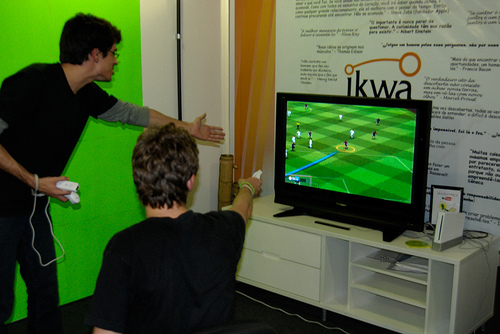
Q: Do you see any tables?
A: Yes, there is a table.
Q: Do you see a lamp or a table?
A: Yes, there is a table.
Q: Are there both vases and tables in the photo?
A: No, there is a table but no vases.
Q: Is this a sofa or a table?
A: This is a table.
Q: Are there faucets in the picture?
A: No, there are no faucets.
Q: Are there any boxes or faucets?
A: No, there are no faucets or boxes.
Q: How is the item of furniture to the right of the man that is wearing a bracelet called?
A: The piece of furniture is a drawer.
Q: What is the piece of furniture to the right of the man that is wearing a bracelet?
A: The piece of furniture is a drawer.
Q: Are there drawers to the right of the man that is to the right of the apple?
A: Yes, there is a drawer to the right of the man.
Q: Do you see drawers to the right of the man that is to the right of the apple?
A: Yes, there is a drawer to the right of the man.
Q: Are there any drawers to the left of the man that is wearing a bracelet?
A: No, the drawer is to the right of the man.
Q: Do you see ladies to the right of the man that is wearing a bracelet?
A: No, there is a drawer to the right of the man.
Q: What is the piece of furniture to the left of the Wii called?
A: The piece of furniture is a drawer.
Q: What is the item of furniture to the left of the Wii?
A: The piece of furniture is a drawer.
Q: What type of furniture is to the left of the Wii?
A: The piece of furniture is a drawer.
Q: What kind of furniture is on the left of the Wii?
A: The piece of furniture is a drawer.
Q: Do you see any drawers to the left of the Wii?
A: Yes, there is a drawer to the left of the Wii.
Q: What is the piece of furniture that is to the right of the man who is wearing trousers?
A: The piece of furniture is a drawer.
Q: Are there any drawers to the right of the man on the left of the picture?
A: Yes, there is a drawer to the right of the man.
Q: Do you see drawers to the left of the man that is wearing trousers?
A: No, the drawer is to the right of the man.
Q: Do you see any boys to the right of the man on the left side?
A: No, there is a drawer to the right of the man.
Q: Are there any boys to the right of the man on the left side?
A: No, there is a drawer to the right of the man.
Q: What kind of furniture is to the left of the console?
A: The piece of furniture is a drawer.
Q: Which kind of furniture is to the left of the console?
A: The piece of furniture is a drawer.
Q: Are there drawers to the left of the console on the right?
A: Yes, there is a drawer to the left of the console.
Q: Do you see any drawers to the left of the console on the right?
A: Yes, there is a drawer to the left of the console.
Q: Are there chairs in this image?
A: No, there are no chairs.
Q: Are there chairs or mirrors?
A: No, there are no chairs or mirrors.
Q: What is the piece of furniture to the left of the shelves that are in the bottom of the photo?
A: The piece of furniture is a drawer.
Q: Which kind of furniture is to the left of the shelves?
A: The piece of furniture is a drawer.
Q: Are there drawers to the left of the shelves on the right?
A: Yes, there is a drawer to the left of the shelves.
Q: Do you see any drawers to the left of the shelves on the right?
A: Yes, there is a drawer to the left of the shelves.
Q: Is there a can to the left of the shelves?
A: No, there is a drawer to the left of the shelves.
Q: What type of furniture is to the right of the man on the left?
A: The piece of furniture is a drawer.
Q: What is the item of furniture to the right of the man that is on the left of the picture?
A: The piece of furniture is a drawer.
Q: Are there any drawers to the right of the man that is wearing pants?
A: Yes, there is a drawer to the right of the man.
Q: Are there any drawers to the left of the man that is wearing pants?
A: No, the drawer is to the right of the man.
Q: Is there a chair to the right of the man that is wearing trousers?
A: No, there is a drawer to the right of the man.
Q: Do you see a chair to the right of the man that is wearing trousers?
A: No, there is a drawer to the right of the man.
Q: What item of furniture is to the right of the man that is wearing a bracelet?
A: The piece of furniture is a drawer.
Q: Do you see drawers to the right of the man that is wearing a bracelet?
A: Yes, there is a drawer to the right of the man.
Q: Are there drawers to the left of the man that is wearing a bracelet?
A: No, the drawer is to the right of the man.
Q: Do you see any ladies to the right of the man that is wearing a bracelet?
A: No, there is a drawer to the right of the man.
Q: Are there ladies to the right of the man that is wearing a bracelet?
A: No, there is a drawer to the right of the man.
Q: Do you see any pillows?
A: No, there are no pillows.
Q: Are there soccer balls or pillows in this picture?
A: No, there are no pillows or soccer balls.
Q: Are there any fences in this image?
A: No, there are no fences.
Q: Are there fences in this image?
A: No, there are no fences.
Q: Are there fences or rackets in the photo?
A: No, there are no fences or rackets.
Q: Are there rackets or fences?
A: No, there are no fences or rackets.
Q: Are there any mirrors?
A: No, there are no mirrors.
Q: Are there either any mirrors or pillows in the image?
A: No, there are no mirrors or pillows.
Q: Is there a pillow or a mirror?
A: No, there are no mirrors or pillows.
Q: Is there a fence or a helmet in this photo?
A: No, there are no helmets or fences.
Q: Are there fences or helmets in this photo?
A: No, there are no helmets or fences.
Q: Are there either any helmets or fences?
A: No, there are no helmets or fences.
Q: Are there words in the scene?
A: Yes, there are words.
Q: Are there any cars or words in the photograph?
A: Yes, there are words.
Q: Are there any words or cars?
A: Yes, there are words.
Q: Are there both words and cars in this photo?
A: No, there are words but no cars.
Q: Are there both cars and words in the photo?
A: No, there are words but no cars.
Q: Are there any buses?
A: No, there are no buses.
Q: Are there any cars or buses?
A: No, there are no buses or cars.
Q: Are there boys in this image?
A: No, there are no boys.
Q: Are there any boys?
A: No, there are no boys.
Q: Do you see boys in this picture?
A: No, there are no boys.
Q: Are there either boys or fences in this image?
A: No, there are no boys or fences.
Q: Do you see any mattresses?
A: No, there are no mattresses.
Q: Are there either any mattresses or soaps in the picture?
A: No, there are no mattresses or soaps.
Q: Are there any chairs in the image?
A: No, there are no chairs.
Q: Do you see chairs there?
A: No, there are no chairs.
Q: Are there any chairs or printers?
A: No, there are no chairs or printers.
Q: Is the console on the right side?
A: Yes, the console is on the right of the image.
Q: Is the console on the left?
A: No, the console is on the right of the image.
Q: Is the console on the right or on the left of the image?
A: The console is on the right of the image.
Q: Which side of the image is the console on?
A: The console is on the right of the image.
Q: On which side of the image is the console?
A: The console is on the right of the image.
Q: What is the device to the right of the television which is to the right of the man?
A: The device is a console.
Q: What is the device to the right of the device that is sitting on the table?
A: The device is a console.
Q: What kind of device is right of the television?
A: The device is a console.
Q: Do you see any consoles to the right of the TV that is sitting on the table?
A: Yes, there is a console to the right of the television.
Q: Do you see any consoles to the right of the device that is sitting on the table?
A: Yes, there is a console to the right of the television.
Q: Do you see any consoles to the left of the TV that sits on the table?
A: No, the console is to the right of the television.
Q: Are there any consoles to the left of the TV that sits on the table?
A: No, the console is to the right of the television.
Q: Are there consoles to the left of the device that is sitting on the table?
A: No, the console is to the right of the television.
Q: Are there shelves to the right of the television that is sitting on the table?
A: No, there is a console to the right of the TV.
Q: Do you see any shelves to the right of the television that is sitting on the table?
A: No, there is a console to the right of the TV.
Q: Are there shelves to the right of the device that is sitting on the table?
A: No, there is a console to the right of the TV.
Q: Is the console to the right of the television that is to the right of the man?
A: Yes, the console is to the right of the TV.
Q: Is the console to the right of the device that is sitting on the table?
A: Yes, the console is to the right of the TV.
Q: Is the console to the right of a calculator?
A: No, the console is to the right of the TV.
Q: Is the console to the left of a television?
A: No, the console is to the right of a television.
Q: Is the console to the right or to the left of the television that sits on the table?
A: The console is to the right of the TV.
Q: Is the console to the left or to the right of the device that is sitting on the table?
A: The console is to the right of the TV.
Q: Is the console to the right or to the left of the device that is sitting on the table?
A: The console is to the right of the TV.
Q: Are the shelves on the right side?
A: Yes, the shelves are on the right of the image.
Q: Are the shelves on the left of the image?
A: No, the shelves are on the right of the image.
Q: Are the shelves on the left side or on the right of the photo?
A: The shelves are on the right of the image.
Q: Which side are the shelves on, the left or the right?
A: The shelves are on the right of the image.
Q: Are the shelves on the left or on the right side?
A: The shelves are on the right of the image.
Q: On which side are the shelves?
A: The shelves are on the right of the image.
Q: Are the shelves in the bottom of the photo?
A: Yes, the shelves are in the bottom of the image.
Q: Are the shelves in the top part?
A: No, the shelves are in the bottom of the image.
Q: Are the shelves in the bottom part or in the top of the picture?
A: The shelves are in the bottom of the image.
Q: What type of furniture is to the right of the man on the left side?
A: The pieces of furniture are shelves.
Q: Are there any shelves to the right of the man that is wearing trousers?
A: Yes, there are shelves to the right of the man.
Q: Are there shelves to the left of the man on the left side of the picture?
A: No, the shelves are to the right of the man.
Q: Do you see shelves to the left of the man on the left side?
A: No, the shelves are to the right of the man.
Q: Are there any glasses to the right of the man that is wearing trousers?
A: No, there are shelves to the right of the man.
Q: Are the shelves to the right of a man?
A: Yes, the shelves are to the right of a man.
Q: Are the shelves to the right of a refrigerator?
A: No, the shelves are to the right of a man.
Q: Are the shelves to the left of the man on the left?
A: No, the shelves are to the right of the man.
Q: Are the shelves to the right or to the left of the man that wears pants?
A: The shelves are to the right of the man.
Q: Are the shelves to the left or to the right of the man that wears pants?
A: The shelves are to the right of the man.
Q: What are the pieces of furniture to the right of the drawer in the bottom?
A: The pieces of furniture are shelves.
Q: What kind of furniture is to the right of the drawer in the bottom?
A: The pieces of furniture are shelves.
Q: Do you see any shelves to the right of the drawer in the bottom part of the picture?
A: Yes, there are shelves to the right of the drawer.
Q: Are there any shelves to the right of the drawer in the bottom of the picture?
A: Yes, there are shelves to the right of the drawer.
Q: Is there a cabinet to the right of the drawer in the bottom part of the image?
A: No, there are shelves to the right of the drawer.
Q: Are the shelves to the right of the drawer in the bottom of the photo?
A: Yes, the shelves are to the right of the drawer.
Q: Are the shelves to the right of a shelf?
A: No, the shelves are to the right of the drawer.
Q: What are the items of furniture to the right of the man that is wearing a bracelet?
A: The pieces of furniture are shelves.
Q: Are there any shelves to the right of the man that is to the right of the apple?
A: Yes, there are shelves to the right of the man.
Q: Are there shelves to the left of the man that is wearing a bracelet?
A: No, the shelves are to the right of the man.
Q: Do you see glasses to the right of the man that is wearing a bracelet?
A: No, there are shelves to the right of the man.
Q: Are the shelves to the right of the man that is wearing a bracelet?
A: Yes, the shelves are to the right of the man.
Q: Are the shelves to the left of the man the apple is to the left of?
A: No, the shelves are to the right of the man.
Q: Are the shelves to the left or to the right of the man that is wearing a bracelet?
A: The shelves are to the right of the man.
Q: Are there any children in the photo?
A: No, there are no children.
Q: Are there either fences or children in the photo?
A: No, there are no children or fences.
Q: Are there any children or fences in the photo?
A: No, there are no children or fences.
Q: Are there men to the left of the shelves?
A: Yes, there is a man to the left of the shelves.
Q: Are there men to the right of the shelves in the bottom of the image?
A: No, the man is to the left of the shelves.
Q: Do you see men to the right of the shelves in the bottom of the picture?
A: No, the man is to the left of the shelves.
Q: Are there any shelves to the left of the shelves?
A: No, there is a man to the left of the shelves.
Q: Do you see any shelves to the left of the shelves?
A: No, there is a man to the left of the shelves.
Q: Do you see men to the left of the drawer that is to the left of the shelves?
A: Yes, there is a man to the left of the drawer.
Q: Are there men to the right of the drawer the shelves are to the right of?
A: No, the man is to the left of the drawer.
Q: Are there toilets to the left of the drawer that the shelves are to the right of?
A: No, there is a man to the left of the drawer.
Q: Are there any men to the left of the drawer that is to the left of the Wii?
A: Yes, there is a man to the left of the drawer.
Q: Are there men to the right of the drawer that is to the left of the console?
A: No, the man is to the left of the drawer.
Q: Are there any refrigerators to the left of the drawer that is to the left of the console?
A: No, there is a man to the left of the drawer.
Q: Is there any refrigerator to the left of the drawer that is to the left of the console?
A: No, there is a man to the left of the drawer.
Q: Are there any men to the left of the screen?
A: Yes, there is a man to the left of the screen.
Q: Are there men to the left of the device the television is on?
A: Yes, there is a man to the left of the screen.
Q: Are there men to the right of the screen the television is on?
A: No, the man is to the left of the screen.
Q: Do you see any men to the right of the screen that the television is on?
A: No, the man is to the left of the screen.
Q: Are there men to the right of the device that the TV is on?
A: No, the man is to the left of the screen.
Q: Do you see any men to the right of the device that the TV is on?
A: No, the man is to the left of the screen.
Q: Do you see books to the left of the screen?
A: No, there is a man to the left of the screen.